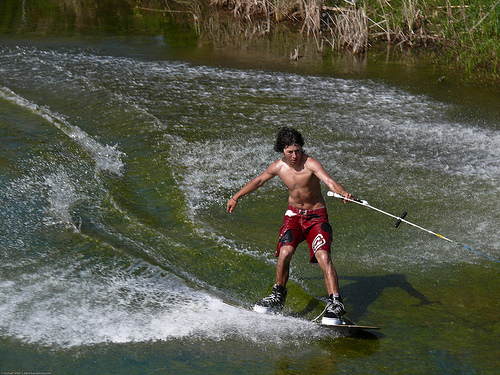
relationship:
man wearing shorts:
[222, 127, 350, 318] [277, 201, 336, 264]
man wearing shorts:
[222, 127, 350, 318] [275, 205, 333, 243]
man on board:
[220, 120, 352, 329] [234, 308, 383, 333]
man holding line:
[220, 120, 352, 329] [320, 179, 499, 279]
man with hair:
[220, 120, 352, 329] [273, 127, 302, 149]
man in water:
[220, 120, 352, 329] [0, 0, 499, 371]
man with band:
[222, 127, 350, 318] [229, 192, 239, 202]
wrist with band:
[228, 190, 236, 204] [229, 192, 239, 202]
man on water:
[222, 127, 350, 318] [0, 0, 499, 371]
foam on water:
[1, 269, 318, 351] [0, 0, 499, 371]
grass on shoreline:
[451, 17, 489, 64] [268, 10, 495, 111]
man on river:
[222, 127, 350, 318] [2, 41, 499, 373]